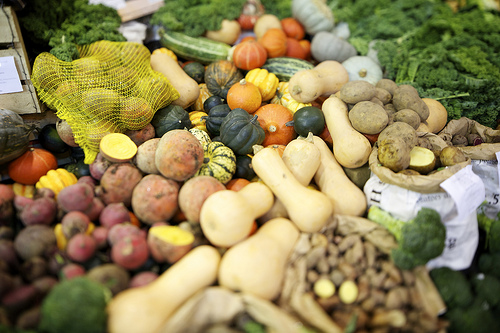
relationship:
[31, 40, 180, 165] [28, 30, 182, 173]
apples in bag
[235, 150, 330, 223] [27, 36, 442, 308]
squash on table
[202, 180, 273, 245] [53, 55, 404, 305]
squash on table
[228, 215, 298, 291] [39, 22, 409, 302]
squash on table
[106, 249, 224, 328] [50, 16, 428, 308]
squash on table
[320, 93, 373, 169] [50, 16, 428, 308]
squash on table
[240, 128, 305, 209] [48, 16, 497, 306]
squash on table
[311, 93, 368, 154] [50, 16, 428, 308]
squash on table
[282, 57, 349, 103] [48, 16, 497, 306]
squash on table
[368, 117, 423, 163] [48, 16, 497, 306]
potato on table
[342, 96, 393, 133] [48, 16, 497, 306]
potato on table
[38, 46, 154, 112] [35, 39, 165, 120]
apples packed nut